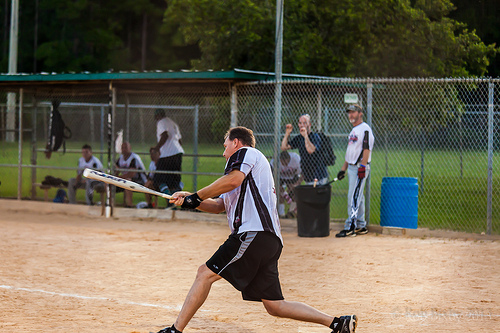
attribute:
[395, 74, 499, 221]
fence — silver, grey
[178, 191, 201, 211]
wristband — black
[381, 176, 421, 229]
trashcan — blue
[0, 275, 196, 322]
chalk line — white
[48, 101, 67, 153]
bag — black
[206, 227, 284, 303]
shorts — black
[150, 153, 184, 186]
shorts — black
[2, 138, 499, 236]
grass — green